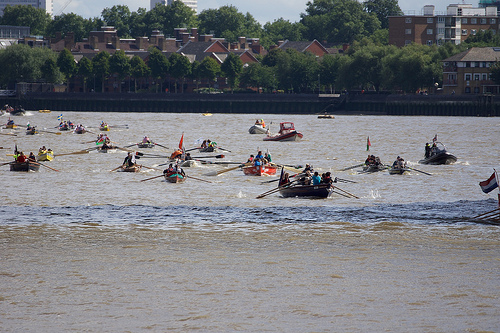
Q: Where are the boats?
A: In the water.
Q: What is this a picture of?
A: Boats.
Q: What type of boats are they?
A: Rowboats.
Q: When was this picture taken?
A: Daytime.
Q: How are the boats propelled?
A: By rowing.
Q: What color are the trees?
A: Green.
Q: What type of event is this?
A: Race.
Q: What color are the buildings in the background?
A: Brown.